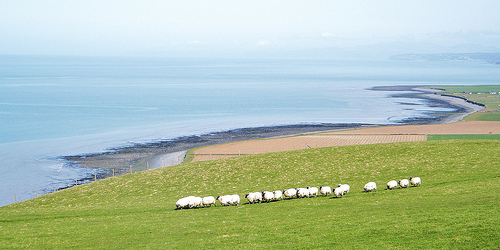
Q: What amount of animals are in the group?
A: Fifteen.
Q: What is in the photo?
A: Sheep.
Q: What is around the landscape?
A: A fence.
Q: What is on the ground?
A: Grass.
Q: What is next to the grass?
A: Water.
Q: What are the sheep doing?
A: Walking.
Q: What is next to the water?
A: Grass.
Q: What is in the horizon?
A: Sky.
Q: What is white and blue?
A: Cloudy sky.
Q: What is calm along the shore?
A: Ocean.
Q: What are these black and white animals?
A: Sheep.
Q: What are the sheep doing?
A: Grazing.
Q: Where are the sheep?
A: Grass.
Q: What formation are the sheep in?
A: Line.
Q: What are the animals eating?
A: Grass.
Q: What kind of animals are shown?
A: Sheep.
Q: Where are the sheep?
A: Walking through a field toward the ocean.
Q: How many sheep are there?
A: 17.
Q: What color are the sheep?
A: White.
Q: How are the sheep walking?
A: In a straight line.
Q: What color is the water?
A: Blue.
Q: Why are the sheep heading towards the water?
A: To get a drink.